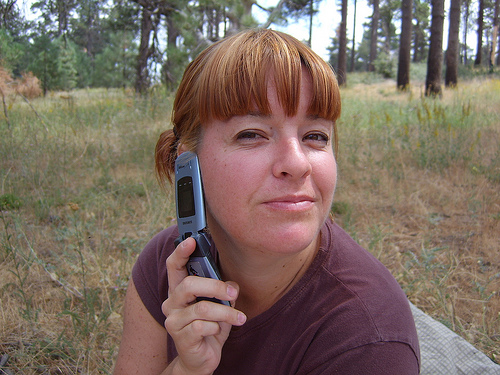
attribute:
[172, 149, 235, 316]
phone — grey, black, cell, silver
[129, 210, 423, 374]
shirt — maroon, cotton, brown, purple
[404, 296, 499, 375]
bench — grey, wood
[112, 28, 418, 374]
girl — talking, sitting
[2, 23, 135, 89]
leaves — green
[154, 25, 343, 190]
hair — red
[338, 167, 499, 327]
weeds — brown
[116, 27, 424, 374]
woman — smiling, sitting, talking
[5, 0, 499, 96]
trees — green, pine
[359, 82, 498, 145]
grasses — long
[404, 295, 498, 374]
log — wooden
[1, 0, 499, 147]
park — wooded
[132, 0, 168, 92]
tree — large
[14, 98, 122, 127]
grass — green, long, yellow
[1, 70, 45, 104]
bush — small, full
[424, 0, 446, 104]
tree — large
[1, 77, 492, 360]
landscape — grassy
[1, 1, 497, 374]
area — large, wooded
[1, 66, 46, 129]
shrub — brown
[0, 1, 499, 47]
sky — hazy